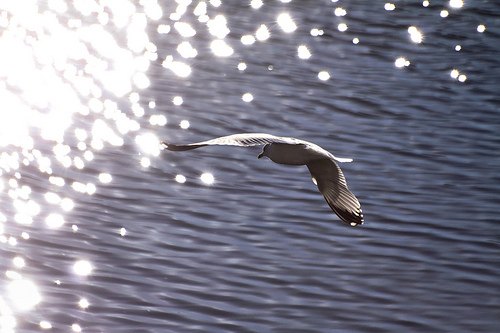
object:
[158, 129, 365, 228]
bird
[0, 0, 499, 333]
water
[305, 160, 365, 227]
wings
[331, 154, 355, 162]
tail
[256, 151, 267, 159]
beak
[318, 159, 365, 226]
feathers